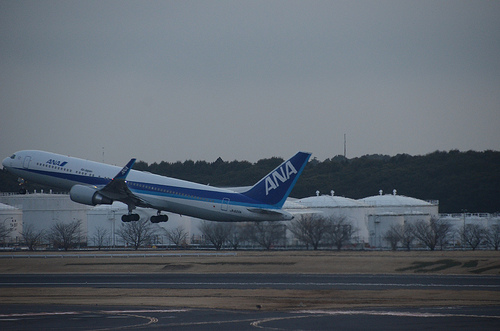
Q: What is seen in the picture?
A: Aeroplane.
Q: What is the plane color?
A: White and blue.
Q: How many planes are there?
A: One.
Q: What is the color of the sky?
A: White.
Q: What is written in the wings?
A: ANA.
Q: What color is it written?
A: Blue.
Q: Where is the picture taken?
A: At the airport.